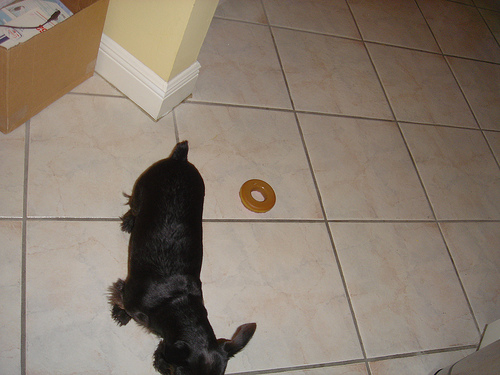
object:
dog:
[116, 145, 242, 353]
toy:
[239, 179, 276, 213]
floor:
[224, 21, 494, 305]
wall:
[107, 3, 166, 65]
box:
[0, 0, 106, 131]